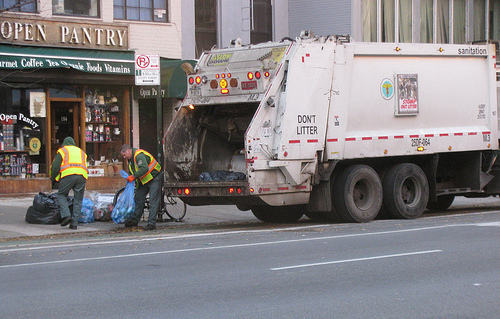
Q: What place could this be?
A: It is a street.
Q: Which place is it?
A: It is a street.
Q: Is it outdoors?
A: Yes, it is outdoors.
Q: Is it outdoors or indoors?
A: It is outdoors.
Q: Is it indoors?
A: No, it is outdoors.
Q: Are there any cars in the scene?
A: No, there are no cars.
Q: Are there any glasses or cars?
A: No, there are no cars or glasses.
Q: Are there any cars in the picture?
A: No, there are no cars.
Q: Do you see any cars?
A: No, there are no cars.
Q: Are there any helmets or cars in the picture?
A: No, there are no cars or helmets.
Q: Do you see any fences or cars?
A: No, there are no cars or fences.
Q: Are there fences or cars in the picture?
A: No, there are no cars or fences.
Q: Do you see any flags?
A: No, there are no flags.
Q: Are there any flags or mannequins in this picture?
A: No, there are no flags or mannequins.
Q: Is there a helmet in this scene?
A: No, there are no helmets.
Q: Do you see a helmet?
A: No, there are no helmets.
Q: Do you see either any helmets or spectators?
A: No, there are no helmets or spectators.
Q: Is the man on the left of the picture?
A: Yes, the man is on the left of the image.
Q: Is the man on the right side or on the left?
A: The man is on the left of the image.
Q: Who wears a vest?
A: The man wears a vest.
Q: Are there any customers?
A: No, there are no customers.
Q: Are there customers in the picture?
A: No, there are no customers.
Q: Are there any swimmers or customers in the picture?
A: No, there are no customers or swimmers.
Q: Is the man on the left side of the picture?
A: Yes, the man is on the left of the image.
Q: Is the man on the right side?
A: No, the man is on the left of the image.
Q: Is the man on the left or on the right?
A: The man is on the left of the image.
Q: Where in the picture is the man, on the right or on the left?
A: The man is on the left of the image.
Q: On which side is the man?
A: The man is on the left of the image.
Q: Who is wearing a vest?
A: The man is wearing a vest.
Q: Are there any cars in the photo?
A: No, there are no cars.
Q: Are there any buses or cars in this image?
A: No, there are no cars or buses.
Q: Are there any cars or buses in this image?
A: No, there are no cars or buses.